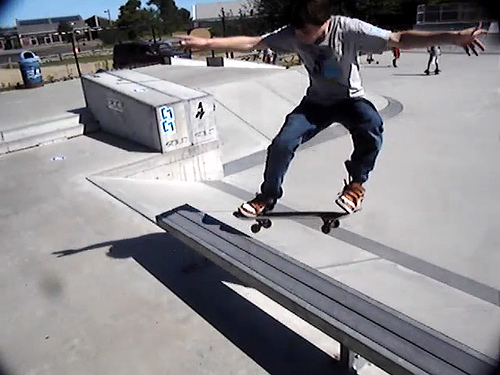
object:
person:
[422, 44, 443, 76]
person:
[389, 39, 401, 68]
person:
[256, 48, 263, 61]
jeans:
[257, 97, 385, 200]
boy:
[168, 0, 492, 219]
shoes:
[333, 181, 368, 215]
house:
[12, 13, 95, 50]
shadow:
[49, 230, 261, 289]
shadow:
[392, 73, 427, 77]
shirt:
[261, 14, 393, 105]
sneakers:
[334, 181, 367, 215]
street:
[0, 77, 83, 130]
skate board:
[231, 207, 364, 235]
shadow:
[130, 253, 363, 375]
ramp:
[84, 175, 500, 375]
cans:
[17, 50, 45, 89]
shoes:
[236, 193, 278, 219]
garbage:
[17, 50, 45, 89]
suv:
[111, 37, 193, 70]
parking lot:
[36, 44, 114, 65]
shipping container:
[79, 68, 220, 155]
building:
[14, 14, 94, 49]